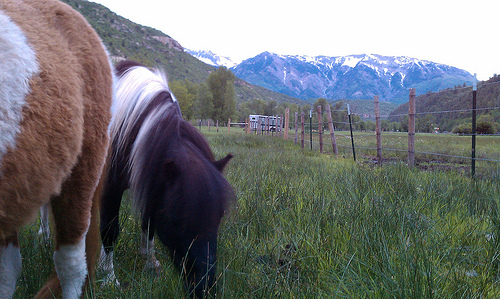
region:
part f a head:
[185, 170, 231, 245]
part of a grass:
[335, 207, 365, 239]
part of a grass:
[318, 248, 336, 268]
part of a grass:
[324, 202, 344, 233]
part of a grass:
[300, 236, 320, 291]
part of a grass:
[341, 187, 357, 222]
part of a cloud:
[434, 29, 444, 44]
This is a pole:
[459, 72, 486, 204]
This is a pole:
[404, 73, 429, 189]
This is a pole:
[369, 80, 390, 172]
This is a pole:
[340, 92, 360, 182]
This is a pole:
[323, 95, 347, 167]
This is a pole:
[312, 97, 327, 160]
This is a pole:
[306, 101, 322, 163]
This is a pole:
[295, 102, 315, 164]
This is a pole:
[290, 99, 304, 146]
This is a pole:
[278, 98, 295, 148]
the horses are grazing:
[4, 3, 236, 280]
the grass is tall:
[330, 199, 449, 284]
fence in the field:
[304, 73, 487, 167]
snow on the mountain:
[269, 43, 449, 91]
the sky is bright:
[272, 4, 389, 49]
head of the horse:
[144, 144, 236, 285]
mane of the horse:
[102, 28, 170, 181]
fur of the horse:
[28, 61, 78, 158]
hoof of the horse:
[147, 246, 167, 266]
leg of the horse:
[50, 215, 115, 295]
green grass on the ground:
[3, 108, 497, 297]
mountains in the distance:
[228, 46, 488, 120]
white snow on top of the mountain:
[339, 53, 363, 68]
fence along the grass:
[178, 65, 498, 181]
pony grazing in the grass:
[99, 49, 258, 295]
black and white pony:
[81, 48, 263, 298]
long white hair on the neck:
[103, 54, 203, 208]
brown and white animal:
[0, 1, 114, 296]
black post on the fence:
[463, 80, 483, 174]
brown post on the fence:
[403, 81, 423, 166]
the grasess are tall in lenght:
[306, 196, 441, 297]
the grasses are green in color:
[275, 176, 431, 286]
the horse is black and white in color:
[121, 51, 246, 281]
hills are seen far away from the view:
[301, 43, 435, 112]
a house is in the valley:
[236, 86, 308, 141]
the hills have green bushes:
[446, 76, 483, 121]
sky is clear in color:
[330, 17, 408, 62]